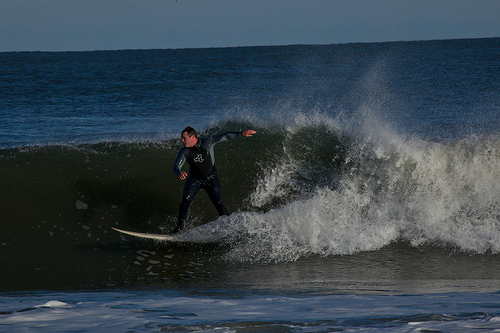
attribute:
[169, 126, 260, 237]
man — surfing, proficient, white, wet, alone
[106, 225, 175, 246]
surfboard — white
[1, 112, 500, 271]
wave — large, big, white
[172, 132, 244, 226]
wet suit — black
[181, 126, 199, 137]
hair — brown, black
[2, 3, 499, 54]
sky — clear, beautiful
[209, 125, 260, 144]
left arm — out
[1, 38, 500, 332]
water — blue